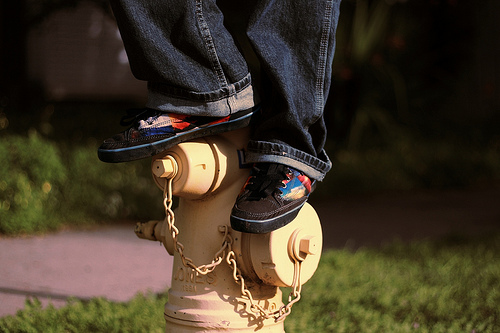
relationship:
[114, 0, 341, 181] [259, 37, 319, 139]
jeans are jeans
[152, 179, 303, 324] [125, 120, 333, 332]
chain on fire hydrant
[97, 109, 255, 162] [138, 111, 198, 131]
shoe have design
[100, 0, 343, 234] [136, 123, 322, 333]
kid standing on hydrant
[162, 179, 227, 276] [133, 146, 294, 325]
chain on hydrant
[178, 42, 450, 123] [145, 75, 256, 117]
jeans with cuffs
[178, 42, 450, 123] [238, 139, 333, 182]
jeans with cuffs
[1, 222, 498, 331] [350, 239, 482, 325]
lawn with grass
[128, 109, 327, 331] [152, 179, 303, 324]
hydrant with chain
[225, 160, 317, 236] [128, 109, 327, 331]
shoe on hydrant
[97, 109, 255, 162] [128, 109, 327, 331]
shoe on hydrant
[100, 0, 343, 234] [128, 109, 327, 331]
kid balancing on hydrant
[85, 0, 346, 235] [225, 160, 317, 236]
kid wearing shoe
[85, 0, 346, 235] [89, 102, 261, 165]
kid wearing shoe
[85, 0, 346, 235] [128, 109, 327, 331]
kid plays on hydrant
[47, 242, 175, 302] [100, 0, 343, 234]
sidewalk behind kid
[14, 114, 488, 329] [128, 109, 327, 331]
grass surrounding hydrant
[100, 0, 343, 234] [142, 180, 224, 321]
kid on hydrant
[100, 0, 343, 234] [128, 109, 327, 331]
kid standing on hydrant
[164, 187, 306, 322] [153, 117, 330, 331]
chain on hydrant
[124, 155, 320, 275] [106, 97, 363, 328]
bolts on hydrant